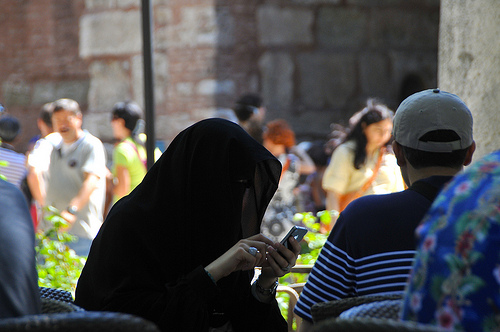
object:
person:
[32, 88, 112, 262]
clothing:
[74, 116, 292, 330]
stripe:
[355, 250, 417, 263]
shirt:
[287, 173, 451, 323]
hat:
[386, 84, 479, 156]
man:
[284, 76, 488, 327]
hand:
[259, 235, 303, 281]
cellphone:
[282, 222, 311, 249]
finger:
[285, 234, 304, 256]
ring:
[247, 243, 260, 259]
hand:
[221, 232, 273, 276]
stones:
[295, 49, 363, 112]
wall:
[0, 2, 442, 145]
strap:
[416, 136, 465, 155]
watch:
[250, 277, 281, 298]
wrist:
[245, 268, 287, 307]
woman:
[318, 94, 408, 214]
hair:
[333, 103, 393, 171]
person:
[67, 105, 304, 332]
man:
[98, 98, 155, 212]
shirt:
[107, 135, 166, 196]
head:
[135, 113, 279, 218]